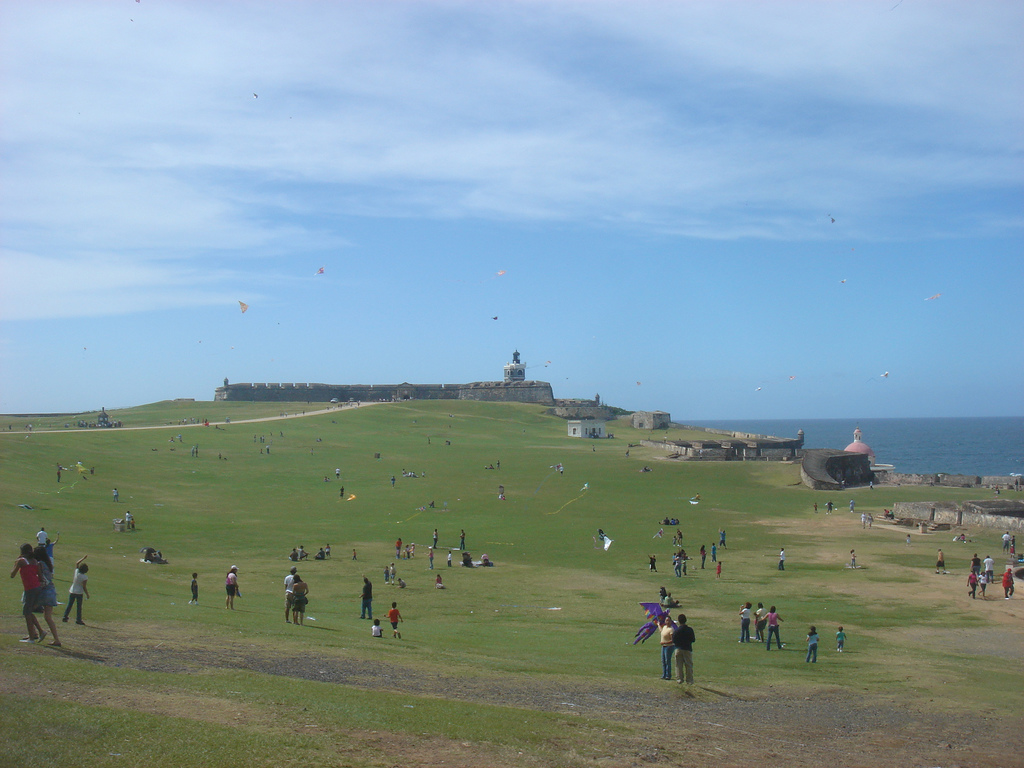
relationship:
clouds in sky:
[0, 0, 1015, 241] [0, 8, 1018, 426]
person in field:
[346, 566, 384, 623] [102, 337, 839, 729]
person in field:
[800, 616, 832, 681] [4, 405, 858, 760]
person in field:
[748, 595, 772, 643] [483, 411, 573, 522]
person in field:
[758, 599, 793, 644] [2, 393, 985, 662]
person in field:
[669, 614, 704, 687] [0, 377, 1016, 764]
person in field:
[800, 616, 821, 671] [0, 377, 1016, 764]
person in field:
[765, 604, 785, 649] [0, 377, 1016, 764]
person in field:
[383, 592, 409, 631] [0, 377, 1016, 764]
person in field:
[60, 558, 95, 622] [0, 377, 1016, 764]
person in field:
[280, 566, 309, 624] [0, 377, 1016, 764]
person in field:
[223, 555, 247, 614] [73, 413, 958, 739]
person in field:
[211, 556, 241, 608] [0, 377, 1016, 764]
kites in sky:
[879, 369, 894, 379] [0, 8, 1018, 426]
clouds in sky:
[724, 365, 767, 408] [0, 8, 1018, 426]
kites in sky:
[189, 248, 578, 361] [0, 8, 1018, 426]